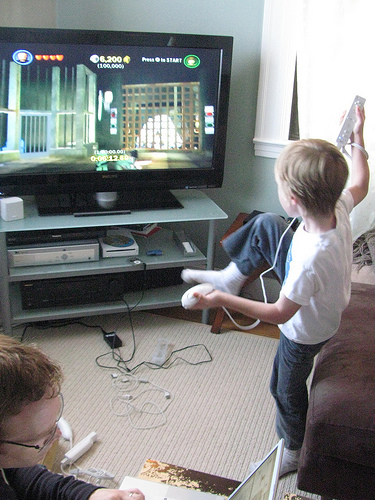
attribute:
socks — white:
[184, 253, 267, 306]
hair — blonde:
[278, 141, 374, 213]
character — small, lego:
[9, 45, 29, 63]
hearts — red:
[21, 49, 62, 74]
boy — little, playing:
[199, 90, 358, 357]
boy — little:
[0, 335, 145, 498]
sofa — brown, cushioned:
[291, 280, 370, 498]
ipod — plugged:
[106, 247, 159, 302]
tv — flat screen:
[0, 36, 246, 237]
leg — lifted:
[162, 201, 271, 294]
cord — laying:
[86, 334, 177, 424]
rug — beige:
[52, 314, 269, 472]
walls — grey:
[194, 6, 262, 128]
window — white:
[239, 0, 361, 184]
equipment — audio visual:
[17, 227, 152, 325]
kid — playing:
[208, 143, 349, 447]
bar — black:
[50, 186, 146, 259]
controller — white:
[47, 410, 106, 484]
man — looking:
[5, 335, 107, 485]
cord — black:
[52, 312, 138, 361]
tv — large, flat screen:
[6, 27, 239, 215]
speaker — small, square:
[83, 184, 125, 211]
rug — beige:
[165, 362, 295, 498]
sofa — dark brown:
[315, 418, 357, 493]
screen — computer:
[226, 456, 281, 495]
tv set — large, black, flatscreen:
[11, 31, 218, 215]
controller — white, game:
[335, 96, 359, 156]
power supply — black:
[100, 330, 120, 350]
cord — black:
[77, 319, 103, 336]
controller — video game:
[62, 434, 117, 467]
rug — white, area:
[100, 347, 267, 460]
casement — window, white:
[268, 1, 285, 150]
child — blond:
[233, 127, 343, 439]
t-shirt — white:
[261, 218, 357, 353]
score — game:
[97, 52, 131, 70]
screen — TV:
[11, 31, 225, 185]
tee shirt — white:
[278, 214, 354, 349]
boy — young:
[220, 159, 338, 466]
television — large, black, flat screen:
[4, 19, 230, 206]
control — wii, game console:
[332, 95, 365, 153]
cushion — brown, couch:
[329, 337, 363, 471]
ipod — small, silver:
[124, 256, 148, 270]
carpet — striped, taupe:
[164, 381, 239, 436]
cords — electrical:
[116, 343, 197, 418]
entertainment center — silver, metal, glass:
[25, 207, 214, 330]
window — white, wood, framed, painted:
[246, 2, 293, 167]